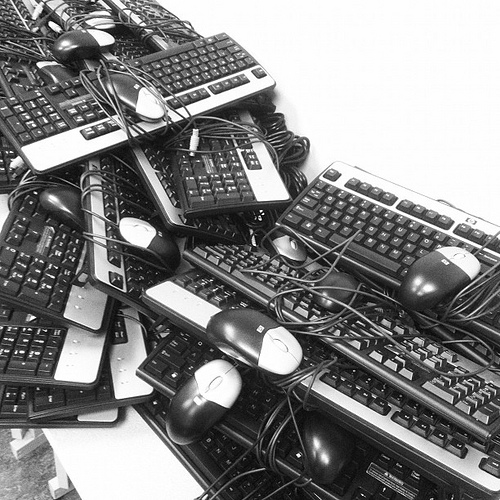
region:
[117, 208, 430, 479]
pile on computer mouses and keyboards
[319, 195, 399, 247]
black key with white letters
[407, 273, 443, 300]
lights shinning on computer mouse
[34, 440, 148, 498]
white smooth wooden desk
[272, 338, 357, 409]
wires covering computer keyboard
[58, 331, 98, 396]
three lights on a keyboard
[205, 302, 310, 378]
white and gray computer mouse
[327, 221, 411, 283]
black space key on keyboard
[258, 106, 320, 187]
lots of black wires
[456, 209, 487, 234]
HP logo on keyboard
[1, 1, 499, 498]
a bunch of keyboards piled on top of each other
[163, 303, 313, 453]
a couple of computer mice resting on top of the keyboards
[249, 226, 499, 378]
a tangled mess of wires on top of the keyboard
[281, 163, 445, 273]
keys on the keyboard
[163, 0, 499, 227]
a plain white wall behind the stacks of keyboards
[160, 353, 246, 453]
a two toned basic computer mouse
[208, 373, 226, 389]
a scrolling button in the middle of the computer mouse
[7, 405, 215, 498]
a table with a lot of keyboards on it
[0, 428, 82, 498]
a floor with a granite pattern on it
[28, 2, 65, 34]
a couple of plugs for the electonics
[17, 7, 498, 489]
keyboards and mouses in a pile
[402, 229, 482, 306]
mouse of a computer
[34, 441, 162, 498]
table where keyboards are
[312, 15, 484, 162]
wall where table is up against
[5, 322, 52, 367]
buttons on a keyboard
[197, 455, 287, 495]
wires to the mouses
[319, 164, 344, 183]
escape button on a keyboard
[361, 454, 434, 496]
warning sticker on a keyboard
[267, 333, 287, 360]
button on a mouse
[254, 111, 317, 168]
wires wrapped behind keyboard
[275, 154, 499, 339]
a black computer keyboard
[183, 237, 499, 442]
a black computer keyboard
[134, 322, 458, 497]
a black computer keyboard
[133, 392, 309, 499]
a black computer keyboard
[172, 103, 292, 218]
a black computer keyboard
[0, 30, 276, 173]
a black computer keyboard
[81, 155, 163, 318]
a black computer keyboard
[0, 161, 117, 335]
a black computer keyboard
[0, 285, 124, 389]
a black computer keyboard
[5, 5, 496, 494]
A large stack of keyboards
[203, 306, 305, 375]
A black and white computer mouse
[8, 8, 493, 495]
A whole bunch of keyboards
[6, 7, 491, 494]
A bunch of computer keyboards and mice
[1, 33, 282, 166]
A black and white keyboard and mouse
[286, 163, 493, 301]
Black keys on a keyboard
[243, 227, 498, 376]
Black wires on top of keyboards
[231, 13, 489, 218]
A white table with keyboards on it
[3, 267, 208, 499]
Keyboards on a white table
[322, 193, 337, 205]
The letter Q on a keyboard